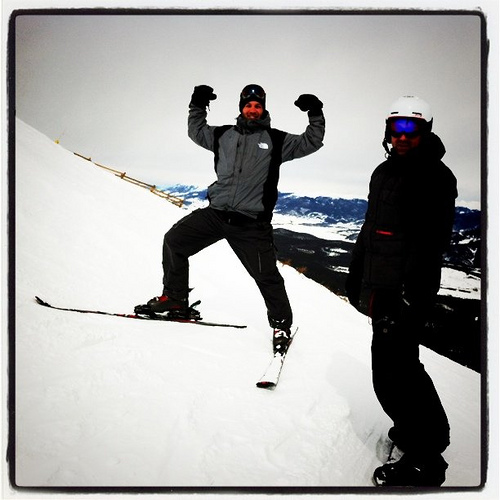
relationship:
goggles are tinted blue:
[387, 120, 425, 140] [395, 118, 418, 134]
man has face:
[346, 95, 482, 486] [389, 121, 425, 154]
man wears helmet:
[346, 95, 482, 486] [386, 94, 434, 135]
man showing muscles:
[144, 83, 324, 356] [188, 107, 325, 158]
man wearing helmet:
[346, 95, 482, 486] [386, 94, 434, 135]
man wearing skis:
[144, 83, 324, 356] [35, 296, 298, 389]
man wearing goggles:
[346, 95, 482, 486] [387, 120, 425, 140]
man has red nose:
[144, 83, 324, 356] [250, 107, 258, 114]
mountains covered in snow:
[14, 118, 482, 486] [13, 115, 482, 486]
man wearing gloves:
[144, 83, 324, 356] [191, 84, 323, 113]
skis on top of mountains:
[35, 296, 298, 389] [14, 118, 482, 486]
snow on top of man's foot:
[274, 345, 281, 348] [273, 328, 292, 352]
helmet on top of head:
[386, 94, 434, 135] [384, 94, 434, 158]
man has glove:
[144, 83, 324, 356] [190, 85, 218, 107]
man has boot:
[144, 83, 324, 356] [147, 293, 190, 310]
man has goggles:
[346, 95, 482, 486] [387, 120, 425, 140]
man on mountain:
[346, 95, 482, 486] [14, 118, 482, 486]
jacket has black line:
[188, 106, 325, 224] [259, 130, 286, 223]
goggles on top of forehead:
[240, 89, 266, 102] [240, 89, 267, 101]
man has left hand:
[144, 83, 324, 356] [294, 95, 323, 111]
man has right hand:
[144, 83, 324, 356] [191, 86, 218, 106]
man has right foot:
[144, 83, 324, 356] [135, 296, 191, 318]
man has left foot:
[144, 83, 324, 356] [273, 328, 292, 352]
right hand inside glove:
[191, 86, 218, 106] [190, 85, 218, 107]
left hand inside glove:
[294, 95, 323, 111] [296, 95, 324, 114]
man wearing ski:
[144, 83, 324, 356] [37, 296, 248, 328]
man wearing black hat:
[144, 83, 324, 356] [240, 84, 267, 108]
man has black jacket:
[346, 95, 482, 486] [345, 133, 460, 335]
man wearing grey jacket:
[144, 83, 324, 356] [188, 106, 325, 224]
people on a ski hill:
[14, 118, 482, 486] [27, 108, 186, 249]